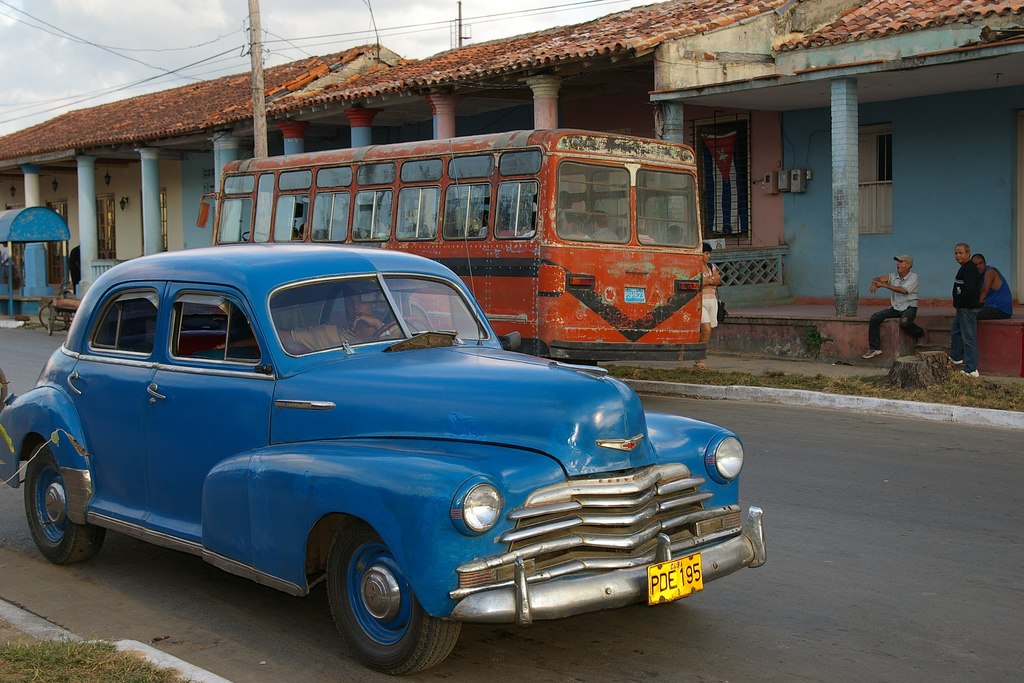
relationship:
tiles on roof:
[105, 78, 244, 118] [1, 40, 373, 177]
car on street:
[16, 237, 786, 626] [79, 306, 993, 628]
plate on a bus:
[632, 550, 719, 602] [195, 129, 702, 361]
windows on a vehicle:
[105, 289, 248, 363] [40, 205, 758, 659]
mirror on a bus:
[187, 183, 216, 238] [187, 138, 713, 327]